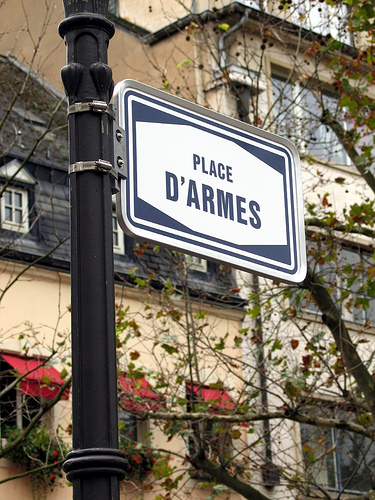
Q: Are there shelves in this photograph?
A: No, there are no shelves.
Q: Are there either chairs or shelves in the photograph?
A: No, there are no shelves or chairs.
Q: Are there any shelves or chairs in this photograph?
A: No, there are no shelves or chairs.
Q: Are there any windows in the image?
A: Yes, there is a window.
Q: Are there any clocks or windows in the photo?
A: Yes, there is a window.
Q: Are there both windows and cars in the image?
A: No, there is a window but no cars.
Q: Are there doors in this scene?
A: No, there are no doors.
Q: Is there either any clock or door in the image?
A: No, there are no doors or clocks.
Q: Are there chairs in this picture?
A: No, there are no chairs.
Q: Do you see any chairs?
A: No, there are no chairs.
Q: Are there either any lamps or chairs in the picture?
A: No, there are no chairs or lamps.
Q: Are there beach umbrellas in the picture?
A: No, there are no beach umbrellas.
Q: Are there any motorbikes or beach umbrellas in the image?
A: No, there are no beach umbrellas or motorbikes.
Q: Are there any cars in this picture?
A: No, there are no cars.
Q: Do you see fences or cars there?
A: No, there are no cars or fences.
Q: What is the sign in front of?
A: The sign is in front of the building.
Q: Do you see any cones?
A: No, there are no cones.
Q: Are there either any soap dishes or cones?
A: No, there are no cones or soap dishes.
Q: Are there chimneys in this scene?
A: No, there are no chimneys.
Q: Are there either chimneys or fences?
A: No, there are no chimneys or fences.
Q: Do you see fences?
A: No, there are no fences.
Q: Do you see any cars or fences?
A: No, there are no fences or cars.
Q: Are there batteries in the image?
A: No, there are no batteries.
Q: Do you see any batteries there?
A: No, there are no batteries.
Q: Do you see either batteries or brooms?
A: No, there are no batteries or brooms.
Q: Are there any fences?
A: No, there are no fences.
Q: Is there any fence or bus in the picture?
A: No, there are no fences or buses.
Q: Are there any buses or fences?
A: No, there are no fences or buses.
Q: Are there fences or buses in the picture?
A: No, there are no fences or buses.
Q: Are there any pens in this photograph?
A: No, there are no pens.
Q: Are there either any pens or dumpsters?
A: No, there are no pens or dumpsters.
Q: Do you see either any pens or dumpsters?
A: No, there are no pens or dumpsters.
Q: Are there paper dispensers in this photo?
A: No, there are no paper dispensers.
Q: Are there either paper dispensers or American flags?
A: No, there are no paper dispensers or American flags.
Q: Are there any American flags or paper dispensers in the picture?
A: No, there are no paper dispensers or American flags.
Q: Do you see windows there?
A: Yes, there is a window.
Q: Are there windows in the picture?
A: Yes, there is a window.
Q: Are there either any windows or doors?
A: Yes, there is a window.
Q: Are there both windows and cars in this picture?
A: No, there is a window but no cars.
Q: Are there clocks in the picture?
A: No, there are no clocks.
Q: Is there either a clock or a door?
A: No, there are no clocks or doors.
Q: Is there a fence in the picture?
A: No, there are no fences.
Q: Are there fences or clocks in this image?
A: No, there are no fences or clocks.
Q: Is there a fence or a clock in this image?
A: No, there are no fences or clocks.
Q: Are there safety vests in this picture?
A: No, there are no safety vests.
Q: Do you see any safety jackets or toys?
A: No, there are no safety jackets or toys.